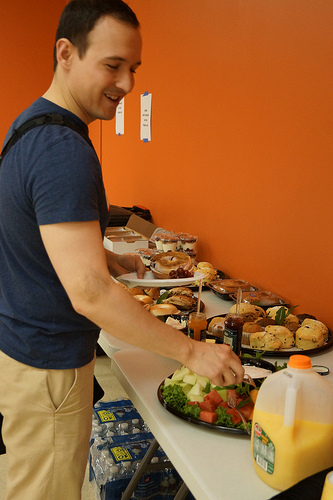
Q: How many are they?
A: 1.